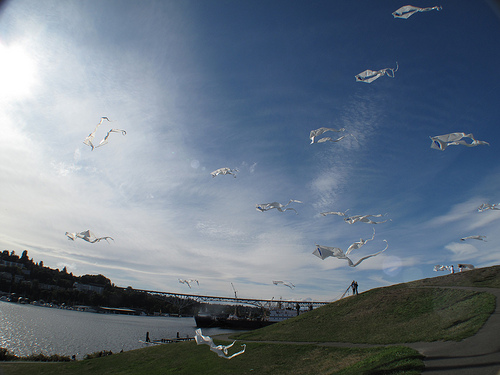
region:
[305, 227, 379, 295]
the kite is white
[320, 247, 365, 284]
the kite is white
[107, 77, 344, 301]
the sky is clear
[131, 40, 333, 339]
the sky is clea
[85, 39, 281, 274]
the sky is clea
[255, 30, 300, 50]
the skies is blue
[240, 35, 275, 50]
the skies is blue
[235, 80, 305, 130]
the skies is blue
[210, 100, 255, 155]
the skies is blue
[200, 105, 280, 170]
the skies is blue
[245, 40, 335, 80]
the skies is blue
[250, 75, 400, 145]
the skies is blue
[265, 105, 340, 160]
the skies is blue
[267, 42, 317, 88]
the skies is blue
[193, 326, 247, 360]
white kite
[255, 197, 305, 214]
white kite against blue sky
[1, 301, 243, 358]
river next to green hill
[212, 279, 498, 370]
paved path on hill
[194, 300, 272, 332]
boat on river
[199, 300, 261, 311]
white canopy on boat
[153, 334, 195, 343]
wood pier in river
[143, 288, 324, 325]
bridge across river in distant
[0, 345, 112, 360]
vegetation near river bank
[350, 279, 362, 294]
person standing on hillside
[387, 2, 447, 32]
white kite flying in air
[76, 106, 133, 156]
white kite flying in air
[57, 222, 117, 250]
white kite flying in air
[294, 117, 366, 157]
white kite flying in air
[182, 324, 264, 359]
white kite flying in air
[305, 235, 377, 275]
white kite flying in air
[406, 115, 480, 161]
white kite flying in air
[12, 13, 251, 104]
sun against blue sky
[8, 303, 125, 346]
calm blue river